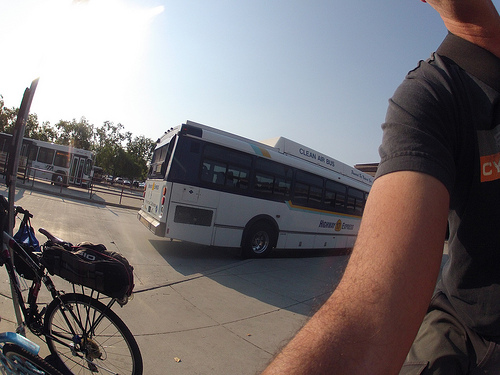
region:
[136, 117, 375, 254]
A white and black bus next to a man in black.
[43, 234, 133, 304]
A long black bag on a bicycle.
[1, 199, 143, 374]
Bicycle with a bag on the back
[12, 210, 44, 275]
Blue and black bag hanging on a handlebar.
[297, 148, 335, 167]
Clean air bus written on the side of the bus.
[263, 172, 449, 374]
The right bare arm of a person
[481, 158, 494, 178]
The white letter C on a black shirt.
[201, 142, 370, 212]
Black windows down the side of the closest bus.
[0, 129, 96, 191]
The white bus furthest away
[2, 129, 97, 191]
A white bus with double doors further away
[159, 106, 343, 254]
white bus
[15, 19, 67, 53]
white clouds in blue sky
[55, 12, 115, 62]
white clouds in blue sky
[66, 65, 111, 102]
white clouds in blue sky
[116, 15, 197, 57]
white clouds in blue sky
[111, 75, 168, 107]
white clouds in blue skywhite clouds in blue sky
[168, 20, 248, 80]
white clouds in blue sky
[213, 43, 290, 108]
white clouds in blue sky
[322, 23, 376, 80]
white clouds in blue sky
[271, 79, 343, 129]
white clouds in blue sky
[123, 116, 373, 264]
white and black bus on road surface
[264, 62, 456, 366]
right arm of man with short black sleeve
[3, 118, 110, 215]
white and black bus in the background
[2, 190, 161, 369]
bicycle with bracket in back with bag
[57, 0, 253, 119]
bright sunlight reflected in a blue sky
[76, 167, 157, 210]
metal railings between roadways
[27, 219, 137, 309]
pack bag on bracket on bicycle rear wheel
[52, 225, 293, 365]
gray cement street with bus on it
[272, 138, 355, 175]
lettered sign on side of bus at the top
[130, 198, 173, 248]
rear bumper of white and black bus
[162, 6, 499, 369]
man taking a photo of himself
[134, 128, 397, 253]
large white passenger bus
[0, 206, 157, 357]
bicycle leaning on a pole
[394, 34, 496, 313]
man wearing a grey t-shirt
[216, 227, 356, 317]
shadow cast on ground by bis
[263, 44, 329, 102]
light blue sky with no clouds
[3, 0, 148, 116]
sunlight shining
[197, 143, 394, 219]
long row of passenger windows on bus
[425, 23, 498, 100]
black strap around man's neck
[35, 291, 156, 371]
metal spokes in the center of wheel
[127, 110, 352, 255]
white bus at curb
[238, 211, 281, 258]
one black bus wheel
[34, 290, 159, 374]
back black bicycle tire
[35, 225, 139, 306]
bag on back of bicycle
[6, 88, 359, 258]
two large white buses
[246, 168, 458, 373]
one Caucasian right male arm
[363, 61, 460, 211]
one short black short sleeve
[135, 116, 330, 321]
white bus casting shadow on sidewalk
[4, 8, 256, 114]
sun glare over blue sky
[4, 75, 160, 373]
bicycles parked by street sign